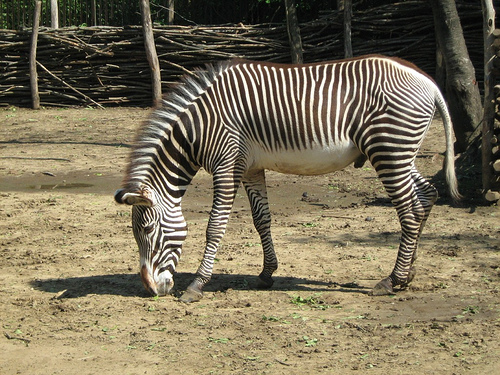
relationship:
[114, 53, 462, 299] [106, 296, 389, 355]
animal sniffing ground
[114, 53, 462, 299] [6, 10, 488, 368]
animal in zoo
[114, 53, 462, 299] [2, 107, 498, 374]
animal eating off ground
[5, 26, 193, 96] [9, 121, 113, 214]
sticks stacked on ground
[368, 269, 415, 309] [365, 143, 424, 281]
hoof on back leg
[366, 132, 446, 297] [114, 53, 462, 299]
back legs are on animal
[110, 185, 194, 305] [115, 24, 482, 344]
head on zebra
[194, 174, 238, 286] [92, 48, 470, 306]
front leg on zebra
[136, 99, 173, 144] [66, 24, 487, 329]
mane on zebra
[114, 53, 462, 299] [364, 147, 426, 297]
animal has back leg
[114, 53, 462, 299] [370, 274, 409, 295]
animal has hoof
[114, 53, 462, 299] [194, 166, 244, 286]
animal has front leg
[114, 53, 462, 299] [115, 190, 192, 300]
animal has head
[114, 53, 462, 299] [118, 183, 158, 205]
animal has ear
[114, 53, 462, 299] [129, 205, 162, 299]
animal has face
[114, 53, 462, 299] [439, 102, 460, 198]
animal has tail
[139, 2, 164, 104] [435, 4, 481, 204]
tree has trunk